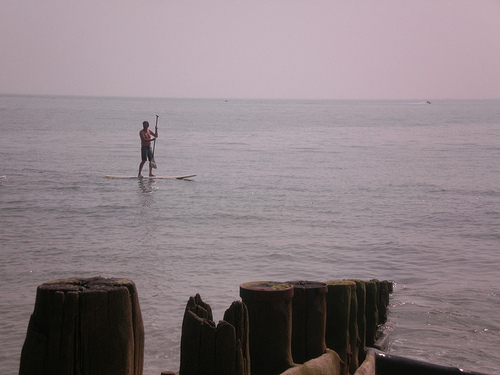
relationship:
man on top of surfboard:
[134, 119, 159, 181] [97, 169, 200, 192]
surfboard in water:
[97, 169, 200, 192] [200, 95, 494, 256]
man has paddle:
[134, 119, 159, 181] [152, 112, 159, 170]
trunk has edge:
[370, 348, 463, 369] [377, 352, 434, 368]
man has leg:
[134, 119, 159, 181] [137, 160, 148, 183]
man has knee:
[134, 119, 159, 181] [138, 161, 145, 170]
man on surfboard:
[134, 119, 159, 181] [97, 169, 200, 192]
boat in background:
[220, 96, 231, 105] [2, 77, 498, 128]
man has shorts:
[134, 119, 159, 181] [140, 148, 161, 166]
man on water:
[134, 119, 159, 181] [200, 95, 494, 256]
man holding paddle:
[134, 119, 159, 181] [152, 112, 159, 170]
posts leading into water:
[18, 265, 394, 369] [200, 95, 494, 256]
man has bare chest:
[134, 119, 159, 181] [138, 130, 154, 146]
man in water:
[134, 119, 159, 181] [200, 95, 494, 256]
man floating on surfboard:
[134, 119, 159, 181] [97, 169, 200, 192]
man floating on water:
[134, 119, 159, 181] [200, 95, 494, 256]